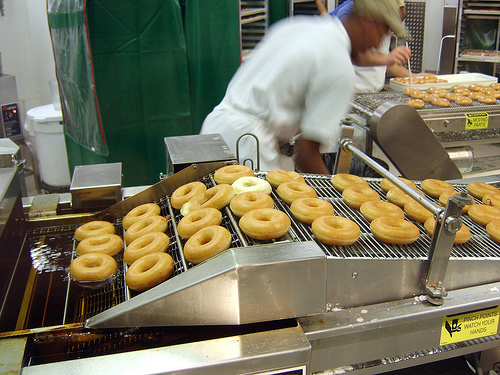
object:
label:
[437, 303, 499, 347]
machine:
[0, 101, 499, 374]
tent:
[44, 0, 239, 190]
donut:
[226, 190, 276, 217]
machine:
[343, 66, 499, 189]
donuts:
[402, 98, 422, 108]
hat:
[341, 0, 409, 39]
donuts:
[436, 77, 448, 84]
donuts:
[396, 81, 411, 87]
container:
[386, 71, 500, 94]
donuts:
[176, 182, 232, 218]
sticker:
[463, 110, 490, 132]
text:
[466, 326, 488, 336]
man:
[196, 0, 406, 177]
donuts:
[452, 94, 472, 106]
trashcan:
[22, 102, 70, 193]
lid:
[20, 103, 63, 124]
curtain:
[83, 1, 242, 187]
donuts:
[120, 200, 160, 231]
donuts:
[328, 171, 368, 190]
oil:
[0, 213, 94, 334]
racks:
[256, 170, 500, 305]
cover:
[43, 0, 108, 190]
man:
[325, 0, 436, 96]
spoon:
[401, 38, 413, 85]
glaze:
[302, 283, 499, 345]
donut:
[310, 213, 359, 246]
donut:
[71, 219, 116, 240]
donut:
[125, 250, 175, 292]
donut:
[121, 231, 170, 264]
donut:
[122, 213, 169, 244]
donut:
[287, 196, 334, 223]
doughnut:
[67, 251, 116, 284]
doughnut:
[230, 175, 274, 194]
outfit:
[198, 11, 355, 176]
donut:
[366, 216, 420, 245]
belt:
[0, 160, 499, 338]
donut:
[210, 163, 256, 183]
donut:
[340, 184, 379, 207]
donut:
[236, 207, 290, 240]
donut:
[75, 230, 123, 256]